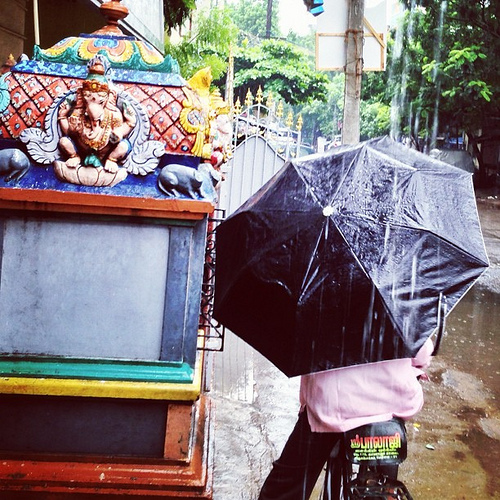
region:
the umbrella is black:
[215, 137, 492, 377]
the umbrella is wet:
[210, 145, 489, 384]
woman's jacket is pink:
[293, 334, 446, 442]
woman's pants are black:
[247, 406, 407, 498]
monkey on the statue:
[46, 63, 133, 183]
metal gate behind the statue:
[222, 89, 302, 219]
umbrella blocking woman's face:
[217, 117, 487, 376]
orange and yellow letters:
[342, 419, 412, 462]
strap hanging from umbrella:
[425, 284, 455, 366]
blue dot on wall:
[168, 125, 180, 145]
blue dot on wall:
[181, 143, 195, 158]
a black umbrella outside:
[271, 181, 434, 330]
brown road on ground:
[437, 375, 481, 452]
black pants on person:
[291, 428, 321, 495]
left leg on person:
[260, 427, 320, 472]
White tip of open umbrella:
[319, 203, 341, 222]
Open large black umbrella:
[210, 132, 490, 382]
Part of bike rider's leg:
[282, 444, 305, 499]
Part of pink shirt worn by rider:
[293, 360, 418, 439]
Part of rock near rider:
[439, 360, 488, 417]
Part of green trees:
[461, 40, 485, 100]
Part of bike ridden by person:
[317, 420, 424, 499]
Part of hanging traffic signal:
[296, 0, 324, 15]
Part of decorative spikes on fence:
[230, 85, 305, 145]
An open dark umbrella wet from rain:
[213, 134, 488, 379]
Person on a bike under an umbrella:
[216, 134, 491, 497]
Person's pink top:
[298, 341, 433, 431]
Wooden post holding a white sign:
[315, 2, 387, 152]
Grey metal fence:
[217, 85, 303, 218]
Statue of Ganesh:
[57, 58, 139, 174]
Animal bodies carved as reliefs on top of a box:
[0, 147, 204, 200]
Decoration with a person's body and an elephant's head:
[56, 57, 138, 172]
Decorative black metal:
[198, 209, 227, 354]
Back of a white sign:
[312, 0, 387, 70]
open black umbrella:
[219, 113, 495, 388]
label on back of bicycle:
[338, 422, 416, 475]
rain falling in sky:
[317, 288, 416, 380]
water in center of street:
[441, 268, 499, 499]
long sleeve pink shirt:
[281, 331, 441, 445]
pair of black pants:
[240, 408, 409, 495]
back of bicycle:
[308, 428, 428, 498]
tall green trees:
[171, 9, 499, 163]